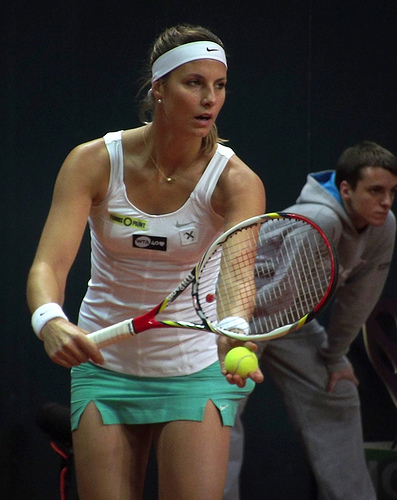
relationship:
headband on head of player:
[151, 40, 227, 80] [26, 23, 267, 499]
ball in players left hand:
[226, 345, 256, 378] [218, 328, 241, 352]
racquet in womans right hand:
[98, 210, 336, 348] [36, 318, 101, 367]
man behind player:
[262, 132, 397, 499] [26, 23, 267, 499]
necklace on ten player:
[138, 126, 172, 182] [26, 23, 267, 499]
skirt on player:
[70, 365, 239, 430] [26, 23, 267, 499]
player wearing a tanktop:
[26, 23, 267, 499] [79, 128, 235, 376]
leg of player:
[70, 409, 151, 499] [26, 23, 267, 499]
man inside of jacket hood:
[262, 132, 397, 499] [293, 168, 341, 205]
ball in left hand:
[226, 345, 256, 378] [218, 328, 241, 352]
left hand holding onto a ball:
[218, 328, 241, 352] [226, 345, 256, 378]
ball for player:
[226, 345, 256, 378] [26, 23, 267, 499]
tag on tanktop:
[108, 212, 148, 226] [79, 128, 235, 376]